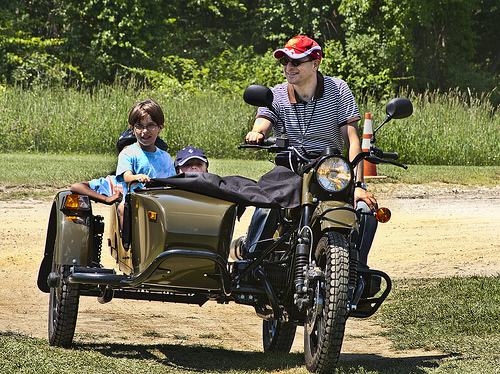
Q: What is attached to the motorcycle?
A: Sidecar.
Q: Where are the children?
A: The sidecar.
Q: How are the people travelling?
A: By motorcycle.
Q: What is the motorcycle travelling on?
A: Dirt road.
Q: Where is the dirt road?
A: Under the motorcycle.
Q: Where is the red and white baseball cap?
A: On the man's head.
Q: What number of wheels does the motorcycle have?
A: 3.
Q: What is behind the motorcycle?
A: Trees.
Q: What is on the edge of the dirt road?
A: Traffic cone.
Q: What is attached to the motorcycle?
A: Side car.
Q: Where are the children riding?
A: Sidecar.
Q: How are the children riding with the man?
A: Sidecar on motorcycle.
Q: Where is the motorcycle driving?
A: Dirt road.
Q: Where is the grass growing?
A: Side of road.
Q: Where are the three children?
A: Sidecar.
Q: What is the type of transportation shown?
A: Motorcycle.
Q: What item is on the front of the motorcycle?
A: Headlight.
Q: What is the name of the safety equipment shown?
A: Cone.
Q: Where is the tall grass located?
A: Distance.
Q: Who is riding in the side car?
A: Children.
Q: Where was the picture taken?
A: On a dirt road.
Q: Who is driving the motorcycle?
A: A man.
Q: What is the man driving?
A: A motorcycle.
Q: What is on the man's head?
A: A hat.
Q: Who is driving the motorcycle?
A: A man.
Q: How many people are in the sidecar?
A: Three.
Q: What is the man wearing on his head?
A: A hat.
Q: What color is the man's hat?
A: Red.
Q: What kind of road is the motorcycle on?
A: Dirt.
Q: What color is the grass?
A: Green.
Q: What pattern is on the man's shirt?
A: Stripes.